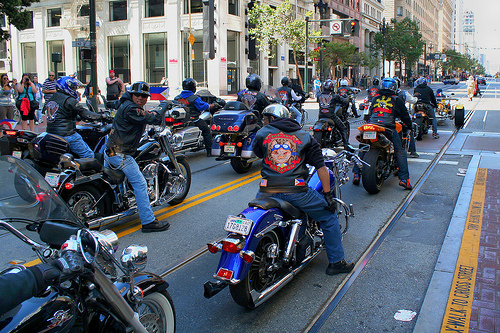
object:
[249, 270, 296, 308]
muffler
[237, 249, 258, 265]
light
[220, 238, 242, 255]
brake light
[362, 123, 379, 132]
brake light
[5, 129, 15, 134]
brake light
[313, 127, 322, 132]
brake light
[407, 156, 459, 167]
line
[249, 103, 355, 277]
man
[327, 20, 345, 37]
sign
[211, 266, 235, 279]
red lights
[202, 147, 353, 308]
motorcycle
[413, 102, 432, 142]
motorcycle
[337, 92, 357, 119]
motorcycle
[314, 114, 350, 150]
motorcycle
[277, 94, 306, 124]
motorcycle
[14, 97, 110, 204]
motorcycle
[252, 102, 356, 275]
riders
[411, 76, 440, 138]
riders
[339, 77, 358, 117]
riders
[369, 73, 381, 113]
riders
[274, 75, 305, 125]
riders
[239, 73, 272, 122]
riders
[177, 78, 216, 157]
riders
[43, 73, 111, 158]
man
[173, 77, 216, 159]
man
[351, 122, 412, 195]
motorcycle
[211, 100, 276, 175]
motorcycle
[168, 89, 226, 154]
motorcycle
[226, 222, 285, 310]
wheel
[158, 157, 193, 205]
wheel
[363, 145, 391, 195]
wheel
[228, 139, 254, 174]
wheel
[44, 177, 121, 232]
wheel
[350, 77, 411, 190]
person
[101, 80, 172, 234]
person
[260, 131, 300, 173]
design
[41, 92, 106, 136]
jacket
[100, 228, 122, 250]
lights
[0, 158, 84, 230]
windshield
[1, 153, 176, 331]
motorcycle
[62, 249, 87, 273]
glove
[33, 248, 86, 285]
hand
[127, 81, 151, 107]
head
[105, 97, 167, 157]
leather jacket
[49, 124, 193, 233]
motorcycle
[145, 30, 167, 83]
windows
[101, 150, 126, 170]
chain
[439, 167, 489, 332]
line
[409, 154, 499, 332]
sidewalk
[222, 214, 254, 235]
license plate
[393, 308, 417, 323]
trash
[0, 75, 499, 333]
ground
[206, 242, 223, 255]
light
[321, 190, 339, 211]
hand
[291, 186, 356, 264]
leg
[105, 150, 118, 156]
wallet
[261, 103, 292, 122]
helmet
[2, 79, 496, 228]
stop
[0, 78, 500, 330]
road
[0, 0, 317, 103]
building